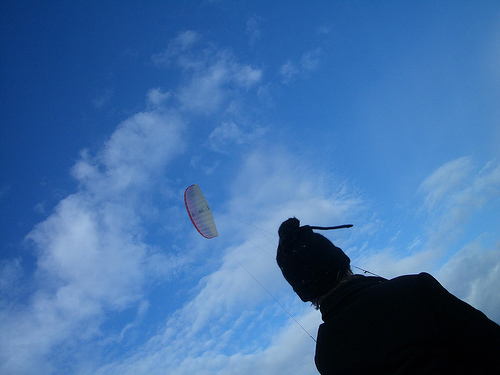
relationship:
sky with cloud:
[0, 5, 500, 374] [276, 47, 322, 88]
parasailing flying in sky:
[184, 184, 219, 240] [0, 5, 500, 374]